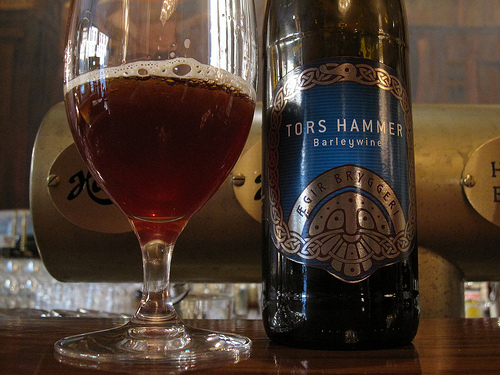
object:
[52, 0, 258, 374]
glass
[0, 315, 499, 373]
wood counter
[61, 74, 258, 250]
wine